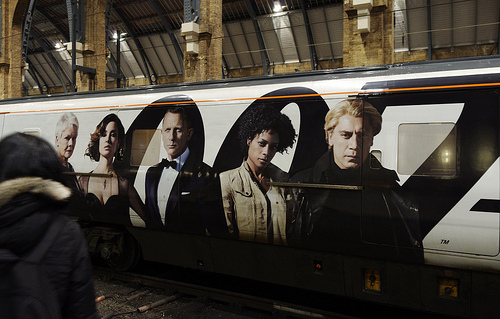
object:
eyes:
[164, 128, 181, 132]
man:
[143, 107, 229, 241]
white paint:
[9, 106, 53, 130]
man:
[284, 97, 424, 260]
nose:
[348, 134, 361, 151]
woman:
[217, 107, 306, 247]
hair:
[237, 100, 298, 155]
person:
[0, 130, 101, 319]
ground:
[353, 72, 498, 242]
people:
[54, 99, 430, 267]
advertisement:
[52, 99, 425, 269]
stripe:
[0, 82, 499, 114]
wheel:
[88, 230, 142, 277]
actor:
[212, 108, 301, 247]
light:
[180, 22, 199, 55]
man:
[144, 108, 233, 241]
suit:
[145, 146, 233, 240]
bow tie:
[161, 158, 177, 169]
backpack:
[0, 214, 69, 319]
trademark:
[440, 239, 449, 244]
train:
[0, 56, 499, 319]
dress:
[74, 170, 150, 241]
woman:
[74, 113, 149, 256]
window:
[396, 122, 457, 177]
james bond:
[0, 54, 499, 319]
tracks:
[1, 260, 500, 318]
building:
[0, 0, 499, 103]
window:
[280, 46, 300, 63]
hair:
[324, 99, 383, 151]